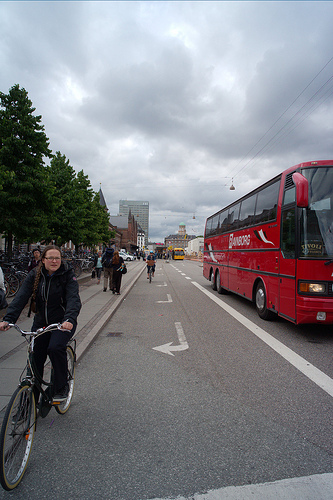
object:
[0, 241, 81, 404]
woman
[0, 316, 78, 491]
bike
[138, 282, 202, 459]
road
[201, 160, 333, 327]
bus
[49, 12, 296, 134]
sky